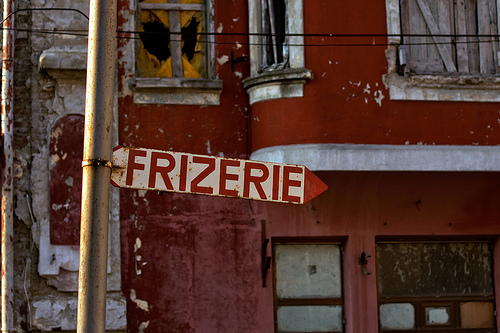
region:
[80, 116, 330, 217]
a sign is on a stainless steel pole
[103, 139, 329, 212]
the directional sign is red and white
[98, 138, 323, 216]
the sign is white with red lettering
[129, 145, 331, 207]
the sign has an arrow on the end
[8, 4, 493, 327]
a run down building is behind the sign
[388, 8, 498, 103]
the window frames are crumbling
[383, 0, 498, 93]
the window is boarded up with 1x2's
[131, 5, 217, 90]
yellow plastic on the window is torn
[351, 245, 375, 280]
a broken light fixture is on the wall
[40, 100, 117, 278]
an arched window is boarded up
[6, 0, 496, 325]
an old red building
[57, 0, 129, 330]
a gray pole in front a building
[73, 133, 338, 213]
a sign on a pole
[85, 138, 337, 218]
sign points to the right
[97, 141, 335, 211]
edge of sign is red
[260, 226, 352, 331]
door of house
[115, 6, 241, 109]
an old window with yellow curtains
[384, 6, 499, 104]
window is closed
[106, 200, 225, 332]
the paint is peeling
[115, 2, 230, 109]
frame of window is wood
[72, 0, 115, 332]
Round silver colored metal post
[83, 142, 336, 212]
Sign with a direction pointing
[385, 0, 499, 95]
Window masked with wooden plants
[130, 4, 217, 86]
Small window covered with torn yellow polythene material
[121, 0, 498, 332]
Red painted wall with peeling pain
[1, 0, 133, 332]
Wall section with broken slab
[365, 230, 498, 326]
Window made mostly of unclear glass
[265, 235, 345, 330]
Window with glass painted white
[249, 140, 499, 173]
Band of pale white painting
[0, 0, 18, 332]
Thin pipe running down the wall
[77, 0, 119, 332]
the pole for the sign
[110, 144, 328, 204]
the red and white sign sticking out from the pole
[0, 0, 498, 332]
the old looking building behind the sign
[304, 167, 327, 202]
the red point on the sign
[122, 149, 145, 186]
the red letter"F" on the sign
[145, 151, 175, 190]
the red letter "R" on the sign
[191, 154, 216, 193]
the red letter "Z" on the sign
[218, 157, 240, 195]
the red letter "E" on the sign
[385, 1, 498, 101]
the window boarded up with pieces of wood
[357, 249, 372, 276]
the metal object sticking out from the building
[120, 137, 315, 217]
red and white sign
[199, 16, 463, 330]
red building behind sign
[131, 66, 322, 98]
grey frames on windows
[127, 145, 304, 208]
red letters on sign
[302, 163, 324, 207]
red arrow on sign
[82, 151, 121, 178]
rusty connector from sign to pole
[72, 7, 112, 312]
rusty and grey pole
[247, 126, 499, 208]
grey concrete wall behind sign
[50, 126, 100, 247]
red and arched window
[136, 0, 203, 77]
orange and broken window